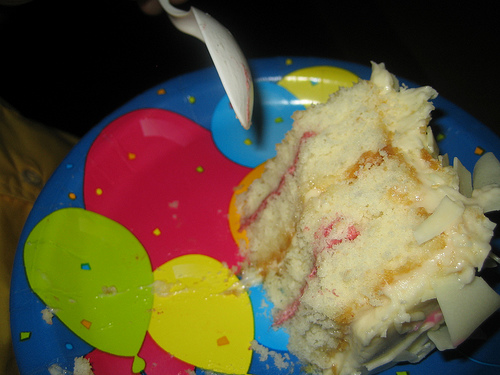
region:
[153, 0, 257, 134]
a white plastic spoon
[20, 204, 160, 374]
a green balloon on the plate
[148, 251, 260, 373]
a yellow balloon on the plate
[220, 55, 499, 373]
a piece of cake on the plate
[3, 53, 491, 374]
a blue paper plate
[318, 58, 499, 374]
white frosting on the cake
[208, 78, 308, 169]
a blue balloon on the plate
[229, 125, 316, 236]
pink frosting in the cake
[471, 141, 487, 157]
an orange speck on the plate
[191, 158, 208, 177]
a green speck on the plate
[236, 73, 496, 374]
A slice of white cake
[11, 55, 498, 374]
A blue plate with balloons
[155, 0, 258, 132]
A white plastic spoon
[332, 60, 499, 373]
White frosting on a cake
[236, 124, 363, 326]
Pink filling in the cake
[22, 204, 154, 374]
A green balloon on a plate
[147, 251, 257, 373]
A yellow balloon on a plate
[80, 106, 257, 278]
A pink pattern on a plate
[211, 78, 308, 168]
A blue balloon on a plate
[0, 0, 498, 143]
A dark shadow in the background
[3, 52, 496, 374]
piece of cake on colorful plate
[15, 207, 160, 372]
green balloon shape on plate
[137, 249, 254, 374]
yellow balloon design on plate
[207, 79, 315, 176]
blue circle on plate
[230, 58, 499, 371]
piece of white cake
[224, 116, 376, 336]
red stripes in cake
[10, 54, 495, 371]
plate with dark blue background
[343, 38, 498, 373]
yellow icing on cake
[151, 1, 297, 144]
spoon used to eat cake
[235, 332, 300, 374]
cake crumbs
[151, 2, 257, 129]
Plastic spoon leaning on plate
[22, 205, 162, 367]
Green ballon picture on plate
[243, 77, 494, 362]
Birthday party cake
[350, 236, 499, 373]
White cream on top of cake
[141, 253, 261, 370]
Yellow balloon on plate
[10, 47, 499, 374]
Blue disposable plate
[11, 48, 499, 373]
Blue plate with birthday cake on it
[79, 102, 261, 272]
Pink ballon on blue paper plate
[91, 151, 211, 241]
Group of four glitters on paper plate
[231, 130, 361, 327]
Pink layer of filling in white cake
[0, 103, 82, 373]
a khaki pant leg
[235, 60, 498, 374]
a half-eaten piece of cake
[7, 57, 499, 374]
a paper party plate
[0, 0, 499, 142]
the room's black background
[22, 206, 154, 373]
a green balloon image on the plate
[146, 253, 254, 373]
a yellow balloon image on the plate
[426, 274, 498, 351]
a white ribbon of frosting on top of the cake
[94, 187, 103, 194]
an image of confetti on the plate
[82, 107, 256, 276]
a red balloon image on the plate